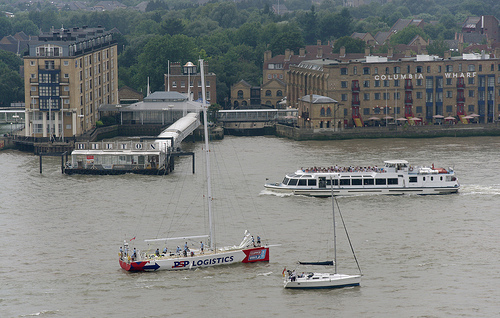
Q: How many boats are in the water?
A: Three.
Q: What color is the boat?
A: Red and white.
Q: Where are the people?
A: On top of the boat.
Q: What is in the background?
A: The building.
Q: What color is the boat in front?
A: Black and white.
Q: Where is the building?
A: It is behind the water.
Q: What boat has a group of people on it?
A: The large boat.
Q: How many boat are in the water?
A: Three.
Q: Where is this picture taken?
A: A river.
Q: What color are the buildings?
A: Yellow.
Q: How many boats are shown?
A: Three.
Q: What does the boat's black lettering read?
A: Logistics.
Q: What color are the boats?
A: White.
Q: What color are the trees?
A: Green.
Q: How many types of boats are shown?
A: Three.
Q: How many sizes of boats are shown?
A: Three.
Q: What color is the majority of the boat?
A: White.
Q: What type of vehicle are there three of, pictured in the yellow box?
A: Boats.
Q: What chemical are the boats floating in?
A: Water.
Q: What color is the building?
A: Tan.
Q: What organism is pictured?
A: Tree.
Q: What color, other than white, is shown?
A: Red.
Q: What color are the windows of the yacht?
A: Black.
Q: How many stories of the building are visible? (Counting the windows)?
A: Six.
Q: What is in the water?
A: Boats.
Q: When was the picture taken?
A: Daytime.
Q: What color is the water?
A: Gray.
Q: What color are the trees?
A: Green.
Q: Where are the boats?
A: In the water.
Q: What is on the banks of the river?
A: Buildings.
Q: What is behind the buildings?
A: Trees.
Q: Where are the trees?
A: Behind the buildings.